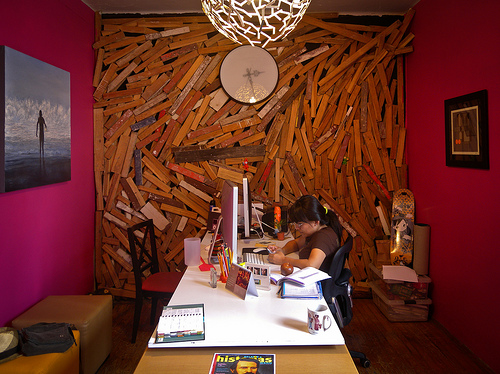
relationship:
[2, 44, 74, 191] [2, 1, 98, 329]
photo on wall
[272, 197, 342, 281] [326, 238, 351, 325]
person sitting in a chair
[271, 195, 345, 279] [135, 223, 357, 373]
woman sitting at desk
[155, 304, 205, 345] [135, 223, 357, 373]
appointment book on desk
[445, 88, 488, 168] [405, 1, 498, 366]
artwork on wall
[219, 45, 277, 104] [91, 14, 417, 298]
clock on wall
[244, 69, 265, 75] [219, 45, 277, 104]
minute hand on clock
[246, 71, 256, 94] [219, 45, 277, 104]
hour hand on clock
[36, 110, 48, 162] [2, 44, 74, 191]
person in photo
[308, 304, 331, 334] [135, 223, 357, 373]
coffee mug on desk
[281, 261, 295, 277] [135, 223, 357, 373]
apple on desk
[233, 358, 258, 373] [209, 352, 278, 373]
man on cover of magazine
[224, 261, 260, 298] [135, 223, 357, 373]
calender opened on desk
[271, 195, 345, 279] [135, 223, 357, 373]
woman working at desk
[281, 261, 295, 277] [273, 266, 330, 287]
apple on notebook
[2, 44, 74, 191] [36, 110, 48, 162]
photo of a person